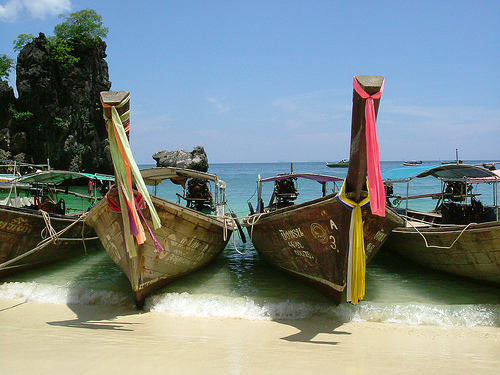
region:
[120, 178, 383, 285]
these are two boats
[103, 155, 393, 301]
the boats are parked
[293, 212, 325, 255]
the boat is wooden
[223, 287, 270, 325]
the waves are small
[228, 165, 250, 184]
the sea is blue in color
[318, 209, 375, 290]
the front is streamlined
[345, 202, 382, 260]
the front has ribbons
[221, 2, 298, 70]
the sky is clear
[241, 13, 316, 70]
the sky is blue in color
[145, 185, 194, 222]
the boat is empty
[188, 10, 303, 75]
The sky is blue.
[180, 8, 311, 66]
The sky is clear.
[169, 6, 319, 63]
The sky is bright.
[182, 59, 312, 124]
A few clouds are in the sky.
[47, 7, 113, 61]
The trees are green.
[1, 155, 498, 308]
The boats are made of wood.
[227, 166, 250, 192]
The water is blue.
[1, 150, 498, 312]
The boats are brown.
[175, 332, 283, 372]
The sand is tan.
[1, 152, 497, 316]
A row of boats.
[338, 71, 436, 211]
a scarf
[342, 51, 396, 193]
a scarf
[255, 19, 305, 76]
part of the sky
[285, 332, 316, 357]
edge of a shade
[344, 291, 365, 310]
edge of a cloth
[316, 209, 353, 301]
edge of a boat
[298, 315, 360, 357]
edge of a shore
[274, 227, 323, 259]
part of a graphic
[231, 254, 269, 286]
part of a water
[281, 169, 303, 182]
edge of a roof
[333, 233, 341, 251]
number 3 is written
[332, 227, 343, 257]
number 3 is written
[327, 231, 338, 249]
number 3 is written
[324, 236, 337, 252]
number 3 is written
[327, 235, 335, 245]
number 3 is written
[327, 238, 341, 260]
number 3 is written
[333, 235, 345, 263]
number 3 is written